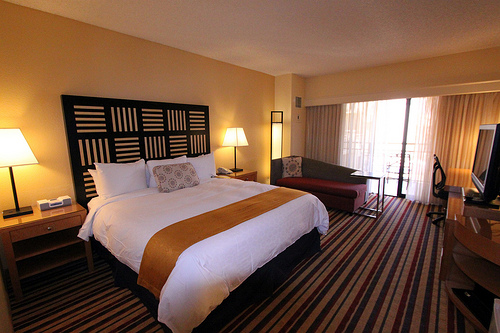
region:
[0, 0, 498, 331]
a luxury hotel suite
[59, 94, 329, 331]
a king size bed in the hotel suite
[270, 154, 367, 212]
a red and grey chaise lounge chair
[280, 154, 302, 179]
a decorative pillow on the chaise lounge chair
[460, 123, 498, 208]
a high definition television on the stand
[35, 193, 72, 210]
a box of Kleenex on the lamp table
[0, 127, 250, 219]
two lamps on wooden tables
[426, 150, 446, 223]
the back of a black chair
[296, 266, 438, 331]
beige, red and green stripped carpeting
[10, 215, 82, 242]
one drawer in front of the lamp table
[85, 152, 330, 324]
a white bed spread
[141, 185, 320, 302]
an orange line on bed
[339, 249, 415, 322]
stripes on the carpet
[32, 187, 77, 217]
a clock on the stand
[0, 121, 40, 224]
a lamp on the stand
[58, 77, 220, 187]
a black head board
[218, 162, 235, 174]
a pwhite phone on the night stand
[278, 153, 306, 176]
a pillow on the couch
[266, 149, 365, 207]
a couch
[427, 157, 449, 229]
a black desk chair.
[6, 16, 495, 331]
a bedroom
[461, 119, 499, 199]
a TV on an entertainment unit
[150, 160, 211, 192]
a pillow with printed circles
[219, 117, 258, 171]
a lamp on a nightstand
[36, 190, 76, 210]
a box of tissue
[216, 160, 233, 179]
a landline phone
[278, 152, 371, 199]
a gray and red couch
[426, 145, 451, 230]
a swiveling black chair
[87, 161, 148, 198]
white pillows on a bed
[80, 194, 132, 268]
white bedding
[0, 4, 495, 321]
A bedroom scene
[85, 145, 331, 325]
This is a bed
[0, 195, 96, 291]
A nightstand is beside the bed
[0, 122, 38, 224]
A lamp is on the stand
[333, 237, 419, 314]
The floor is carpeted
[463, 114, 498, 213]
A flat screen television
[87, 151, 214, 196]
Pillows are on the bed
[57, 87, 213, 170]
The bed's headboard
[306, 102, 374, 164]
Blinds are covering the window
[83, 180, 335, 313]
A blanket is covering the bed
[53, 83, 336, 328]
A beautiful bed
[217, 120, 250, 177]
A bedside lamp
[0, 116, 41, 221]
A bedside lamp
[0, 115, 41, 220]
A bedside lamp with light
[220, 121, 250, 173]
A bedside lamp with light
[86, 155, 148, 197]
Pillow case on the bed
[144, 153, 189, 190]
Pillow case on the bed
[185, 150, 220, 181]
Pillow case on the bed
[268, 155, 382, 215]
A couch in the picture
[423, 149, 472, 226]
A chair in the picture